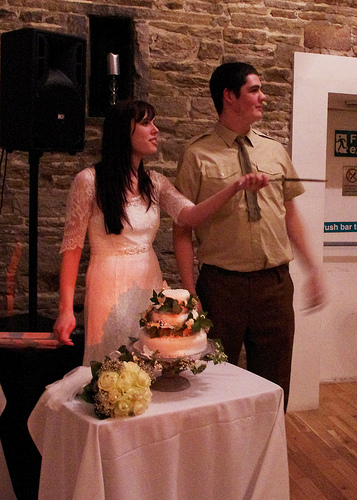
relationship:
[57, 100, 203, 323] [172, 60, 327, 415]
woman standing with man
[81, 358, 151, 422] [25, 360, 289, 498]
flower on table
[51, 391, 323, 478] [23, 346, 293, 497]
table covered by tablecloth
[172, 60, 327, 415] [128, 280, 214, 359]
man standing by cake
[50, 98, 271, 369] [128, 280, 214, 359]
woman standing by cake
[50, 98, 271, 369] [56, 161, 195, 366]
woman wearing dress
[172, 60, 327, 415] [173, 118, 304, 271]
man wearing shirt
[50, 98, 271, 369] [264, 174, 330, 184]
woman holding knife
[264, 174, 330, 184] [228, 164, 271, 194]
knife in hand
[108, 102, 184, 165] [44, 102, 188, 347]
head of woman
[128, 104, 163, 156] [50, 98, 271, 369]
face of woman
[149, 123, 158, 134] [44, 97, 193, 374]
nose of woman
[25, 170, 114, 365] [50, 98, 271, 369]
arm of woman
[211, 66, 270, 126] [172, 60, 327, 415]
face of man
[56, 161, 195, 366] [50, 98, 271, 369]
dress on woman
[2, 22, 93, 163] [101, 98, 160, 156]
speaker near head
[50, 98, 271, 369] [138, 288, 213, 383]
woman standing in front of cake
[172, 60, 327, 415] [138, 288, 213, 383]
man standing in front of cake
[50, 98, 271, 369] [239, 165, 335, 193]
woman holding knife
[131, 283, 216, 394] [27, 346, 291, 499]
cake on table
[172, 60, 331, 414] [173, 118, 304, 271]
man wearing shirt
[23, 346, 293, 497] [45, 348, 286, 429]
tablecloth on table